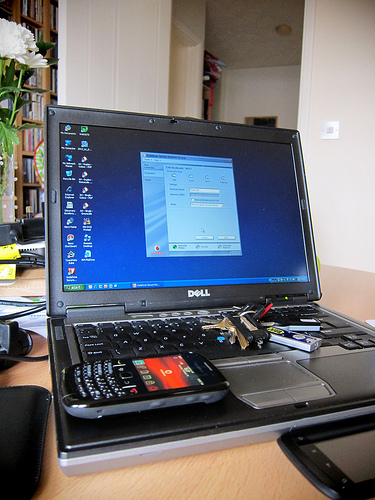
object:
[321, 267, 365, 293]
floor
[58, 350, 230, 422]
phone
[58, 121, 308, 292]
screen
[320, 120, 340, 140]
stat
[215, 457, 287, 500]
table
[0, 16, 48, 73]
flower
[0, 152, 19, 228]
vase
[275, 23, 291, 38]
detector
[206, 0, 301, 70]
ceiling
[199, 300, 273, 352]
key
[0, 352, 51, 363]
cord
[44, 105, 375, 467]
computer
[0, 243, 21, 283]
paper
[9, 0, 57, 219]
shelf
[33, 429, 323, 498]
desk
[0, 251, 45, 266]
wire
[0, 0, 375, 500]
office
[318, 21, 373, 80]
wall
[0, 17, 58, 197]
trim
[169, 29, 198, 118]
door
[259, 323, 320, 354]
chain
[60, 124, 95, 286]
icon